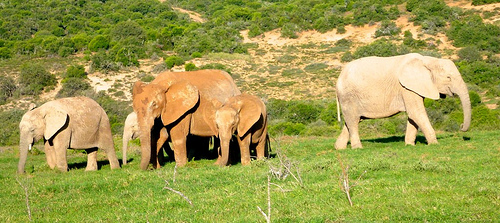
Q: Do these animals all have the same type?
A: Yes, all the animals are elephants.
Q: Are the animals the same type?
A: Yes, all the animals are elephants.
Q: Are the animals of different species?
A: No, all the animals are elephants.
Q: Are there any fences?
A: No, there are no fences.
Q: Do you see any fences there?
A: No, there are no fences.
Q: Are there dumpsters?
A: No, there are no dumpsters.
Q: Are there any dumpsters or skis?
A: No, there are no dumpsters or skis.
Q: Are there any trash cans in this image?
A: No, there are no trash cans.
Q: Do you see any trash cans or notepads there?
A: No, there are no trash cans or notepads.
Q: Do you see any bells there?
A: No, there are no bells.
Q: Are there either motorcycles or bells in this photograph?
A: No, there are no bells or motorcycles.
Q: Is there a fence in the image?
A: No, there are no fences.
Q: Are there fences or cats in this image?
A: No, there are no fences or cats.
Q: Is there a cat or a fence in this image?
A: No, there are no fences or cats.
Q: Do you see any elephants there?
A: Yes, there is an elephant.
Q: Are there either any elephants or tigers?
A: Yes, there is an elephant.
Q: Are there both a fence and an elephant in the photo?
A: No, there is an elephant but no fences.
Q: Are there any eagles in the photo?
A: No, there are no eagles.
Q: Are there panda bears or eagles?
A: No, there are no eagles or panda bears.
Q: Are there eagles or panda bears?
A: No, there are no eagles or panda bears.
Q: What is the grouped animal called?
A: The animal is an elephant.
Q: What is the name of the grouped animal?
A: The animal is an elephant.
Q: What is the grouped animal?
A: The animal is an elephant.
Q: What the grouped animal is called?
A: The animal is an elephant.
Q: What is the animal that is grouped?
A: The animal is an elephant.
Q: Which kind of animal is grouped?
A: The animal is an elephant.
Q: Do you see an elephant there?
A: Yes, there is an elephant.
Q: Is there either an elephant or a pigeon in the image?
A: Yes, there is an elephant.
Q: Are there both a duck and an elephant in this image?
A: No, there is an elephant but no ducks.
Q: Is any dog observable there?
A: No, there are no dogs.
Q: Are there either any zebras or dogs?
A: No, there are no dogs or zebras.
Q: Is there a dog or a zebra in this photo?
A: No, there are no dogs or zebras.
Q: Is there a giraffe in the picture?
A: No, there are no giraffes.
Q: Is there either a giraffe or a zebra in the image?
A: No, there are no giraffes or zebras.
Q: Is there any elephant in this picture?
A: Yes, there is an elephant.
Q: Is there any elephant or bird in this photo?
A: Yes, there is an elephant.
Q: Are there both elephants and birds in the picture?
A: No, there is an elephant but no birds.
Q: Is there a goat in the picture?
A: No, there are no goats.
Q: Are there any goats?
A: No, there are no goats.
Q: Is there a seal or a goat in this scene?
A: No, there are no goats or seals.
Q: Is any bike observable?
A: No, there are no bikes.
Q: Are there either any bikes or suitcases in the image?
A: No, there are no bikes or suitcases.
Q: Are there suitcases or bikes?
A: No, there are no bikes or suitcases.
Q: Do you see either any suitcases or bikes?
A: No, there are no bikes or suitcases.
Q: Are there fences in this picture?
A: No, there are no fences.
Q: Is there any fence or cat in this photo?
A: No, there are no fences or cats.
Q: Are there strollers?
A: No, there are no strollers.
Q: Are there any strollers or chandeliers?
A: No, there are no strollers or chandeliers.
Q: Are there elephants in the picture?
A: Yes, there is an elephant.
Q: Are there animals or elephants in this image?
A: Yes, there is an elephant.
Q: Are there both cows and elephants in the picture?
A: No, there is an elephant but no cows.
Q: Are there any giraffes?
A: No, there are no giraffes.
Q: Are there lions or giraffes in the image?
A: No, there are no giraffes or lions.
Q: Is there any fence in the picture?
A: No, there are no fences.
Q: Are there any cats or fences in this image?
A: No, there are no fences or cats.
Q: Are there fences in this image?
A: No, there are no fences.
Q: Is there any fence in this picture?
A: No, there are no fences.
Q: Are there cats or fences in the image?
A: No, there are no fences or cats.